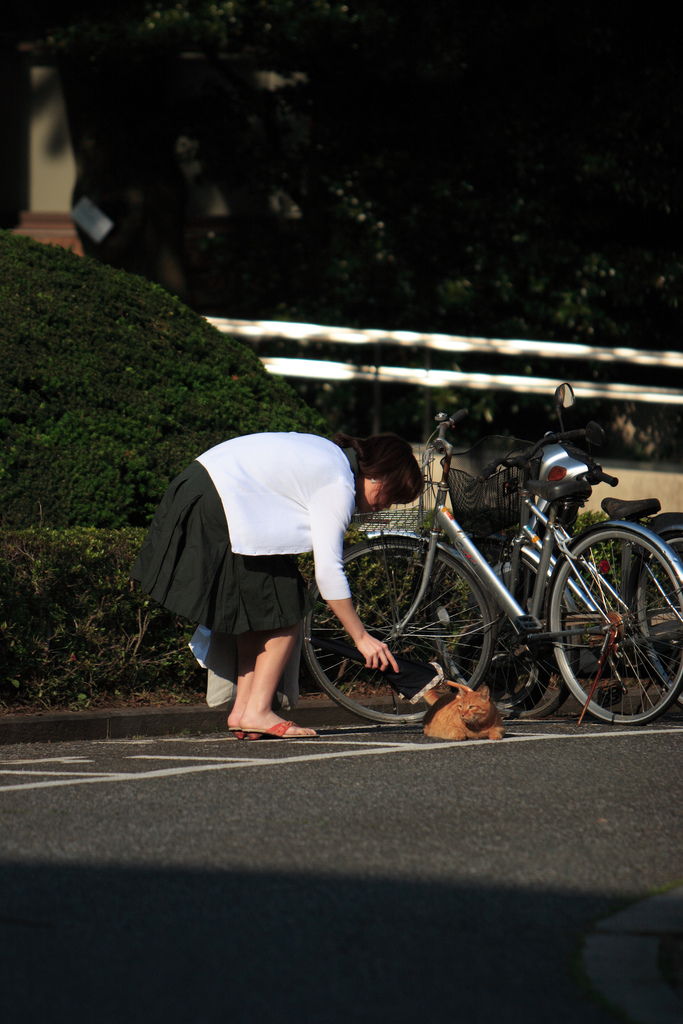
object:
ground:
[0, 719, 683, 1024]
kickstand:
[578, 632, 609, 727]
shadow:
[0, 849, 683, 1020]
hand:
[357, 634, 398, 673]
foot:
[240, 709, 317, 734]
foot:
[228, 707, 245, 726]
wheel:
[547, 521, 683, 726]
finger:
[384, 644, 399, 673]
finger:
[365, 656, 371, 668]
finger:
[372, 651, 378, 668]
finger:
[372, 649, 388, 672]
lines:
[0, 728, 683, 792]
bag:
[440, 435, 544, 537]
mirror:
[554, 382, 575, 432]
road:
[389, 443, 682, 519]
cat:
[424, 686, 506, 740]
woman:
[130, 431, 425, 740]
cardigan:
[195, 432, 357, 601]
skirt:
[131, 460, 317, 637]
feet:
[227, 709, 316, 734]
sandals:
[229, 721, 320, 740]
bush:
[0, 228, 334, 532]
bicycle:
[425, 381, 681, 718]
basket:
[357, 444, 436, 531]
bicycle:
[301, 410, 683, 727]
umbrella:
[304, 637, 473, 705]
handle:
[446, 680, 473, 692]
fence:
[202, 315, 683, 404]